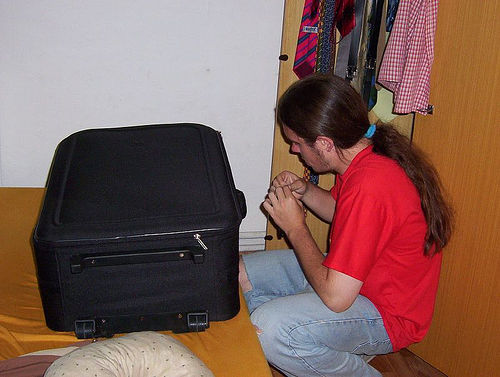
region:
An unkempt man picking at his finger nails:
[229, 79, 485, 371]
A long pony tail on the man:
[366, 122, 458, 235]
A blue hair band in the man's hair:
[363, 119, 382, 141]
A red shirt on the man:
[305, 158, 455, 329]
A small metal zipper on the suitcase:
[189, 234, 219, 252]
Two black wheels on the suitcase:
[69, 315, 214, 337]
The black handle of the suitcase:
[230, 184, 253, 224]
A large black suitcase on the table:
[36, 122, 248, 334]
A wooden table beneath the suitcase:
[0, 178, 272, 370]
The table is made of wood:
[1, 218, 33, 305]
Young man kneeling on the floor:
[234, 65, 446, 374]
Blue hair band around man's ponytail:
[362, 118, 379, 140]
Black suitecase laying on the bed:
[27, 126, 248, 337]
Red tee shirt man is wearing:
[322, 148, 442, 349]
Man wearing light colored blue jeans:
[238, 246, 393, 373]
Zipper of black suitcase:
[107, 219, 233, 238]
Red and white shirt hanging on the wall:
[376, 0, 436, 112]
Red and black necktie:
[291, 0, 321, 75]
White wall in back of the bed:
[0, 0, 285, 252]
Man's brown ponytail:
[374, 118, 454, 255]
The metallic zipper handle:
[193, 233, 208, 248]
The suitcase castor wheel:
[76, 322, 92, 336]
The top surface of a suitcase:
[98, 140, 179, 220]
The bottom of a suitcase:
[92, 271, 191, 306]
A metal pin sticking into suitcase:
[178, 253, 183, 258]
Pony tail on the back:
[426, 181, 444, 231]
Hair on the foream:
[296, 246, 315, 253]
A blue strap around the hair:
[367, 123, 376, 135]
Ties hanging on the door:
[306, 7, 361, 32]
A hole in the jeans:
[255, 327, 260, 334]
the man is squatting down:
[238, 72, 450, 368]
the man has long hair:
[262, 50, 471, 243]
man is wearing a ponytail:
[258, 40, 463, 265]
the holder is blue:
[349, 95, 391, 165]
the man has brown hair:
[277, 47, 470, 244]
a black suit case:
[23, 83, 264, 345]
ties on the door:
[266, 0, 391, 114]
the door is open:
[245, 2, 403, 127]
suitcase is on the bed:
[1, 122, 270, 374]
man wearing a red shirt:
[238, 84, 454, 357]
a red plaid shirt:
[378, 3, 435, 118]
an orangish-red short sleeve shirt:
[322, 143, 436, 353]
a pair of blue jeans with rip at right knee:
[236, 249, 394, 376]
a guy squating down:
[237, 73, 454, 376]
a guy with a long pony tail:
[240, 73, 451, 376]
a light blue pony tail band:
[364, 120, 378, 139]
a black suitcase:
[28, 121, 247, 338]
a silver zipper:
[191, 230, 211, 252]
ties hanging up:
[292, 0, 384, 110]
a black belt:
[364, 1, 382, 108]